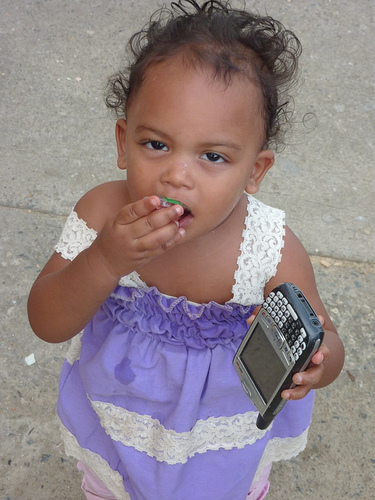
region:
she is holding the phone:
[287, 314, 334, 378]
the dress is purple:
[174, 367, 200, 386]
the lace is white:
[174, 436, 198, 452]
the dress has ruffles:
[164, 295, 202, 332]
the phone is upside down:
[254, 323, 290, 368]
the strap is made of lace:
[249, 217, 274, 260]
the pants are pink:
[88, 477, 98, 494]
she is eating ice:
[143, 193, 188, 215]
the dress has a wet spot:
[107, 353, 141, 385]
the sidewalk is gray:
[325, 437, 354, 468]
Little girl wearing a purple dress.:
[19, 33, 362, 498]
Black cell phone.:
[219, 276, 328, 434]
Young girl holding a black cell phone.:
[12, 10, 361, 438]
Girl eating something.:
[109, 100, 291, 258]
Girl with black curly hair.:
[80, 2, 305, 232]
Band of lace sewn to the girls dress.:
[73, 386, 279, 474]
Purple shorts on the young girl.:
[65, 444, 296, 498]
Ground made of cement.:
[4, 343, 57, 493]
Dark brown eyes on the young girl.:
[129, 127, 237, 169]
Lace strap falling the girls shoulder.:
[53, 177, 129, 285]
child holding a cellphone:
[228, 271, 340, 430]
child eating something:
[138, 181, 230, 268]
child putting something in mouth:
[119, 175, 204, 271]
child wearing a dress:
[24, 150, 365, 498]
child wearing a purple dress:
[14, 167, 374, 498]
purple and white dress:
[35, 174, 338, 497]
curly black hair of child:
[125, 1, 310, 103]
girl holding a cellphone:
[219, 276, 358, 451]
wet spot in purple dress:
[105, 351, 145, 383]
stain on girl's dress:
[111, 353, 143, 400]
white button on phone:
[268, 291, 274, 298]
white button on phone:
[271, 293, 276, 301]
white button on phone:
[276, 299, 281, 309]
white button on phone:
[279, 303, 284, 311]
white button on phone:
[282, 308, 288, 318]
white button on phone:
[263, 296, 271, 303]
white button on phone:
[268, 298, 276, 308]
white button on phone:
[271, 306, 279, 314]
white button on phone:
[279, 313, 285, 322]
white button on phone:
[261, 301, 269, 309]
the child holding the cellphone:
[25, 20, 349, 493]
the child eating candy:
[45, 6, 361, 496]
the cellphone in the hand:
[227, 271, 320, 439]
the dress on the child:
[41, 173, 307, 494]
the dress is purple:
[53, 190, 303, 493]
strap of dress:
[218, 180, 283, 311]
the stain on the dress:
[108, 357, 145, 388]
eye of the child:
[131, 132, 184, 163]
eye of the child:
[193, 138, 238, 171]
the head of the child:
[100, 4, 292, 248]